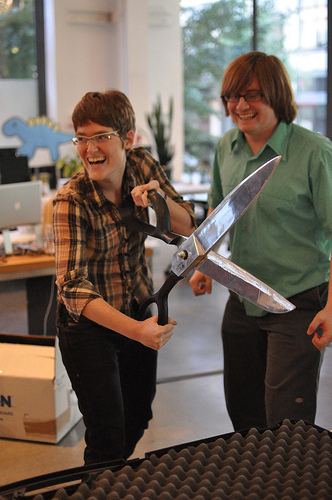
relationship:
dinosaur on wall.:
[2, 117, 77, 162] [133, 33, 165, 77]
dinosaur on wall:
[2, 117, 77, 162] [42, 1, 187, 198]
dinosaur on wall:
[167, 229, 195, 273] [42, 1, 187, 198]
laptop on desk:
[0, 182, 40, 225] [4, 223, 162, 348]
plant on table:
[139, 89, 190, 199] [6, 410, 330, 498]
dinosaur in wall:
[2, 114, 77, 163] [2, 1, 181, 199]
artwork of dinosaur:
[3, 102, 71, 180] [5, 105, 86, 175]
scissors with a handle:
[158, 189, 293, 482] [101, 160, 194, 236]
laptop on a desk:
[0, 178, 45, 228] [0, 232, 56, 271]